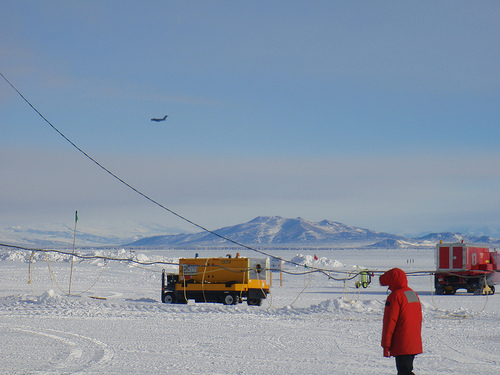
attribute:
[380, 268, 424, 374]
man — standing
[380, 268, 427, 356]
coat — red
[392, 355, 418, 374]
pants — black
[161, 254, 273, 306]
truck — yellow, red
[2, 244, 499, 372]
snow — white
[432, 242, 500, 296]
truck — red, grey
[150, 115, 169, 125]
airplane — here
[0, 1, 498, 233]
sky — clear, blue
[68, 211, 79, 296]
pole — tall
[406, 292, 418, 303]
patch — gray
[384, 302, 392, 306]
patch — black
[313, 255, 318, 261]
flag — red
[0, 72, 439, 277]
cord — long, black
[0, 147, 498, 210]
clouds — white